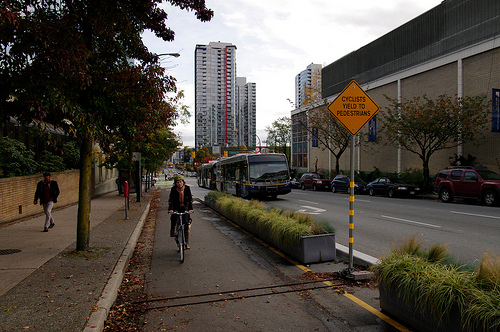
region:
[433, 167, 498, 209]
Red SUV parked on the side of a road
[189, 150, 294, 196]
Two mass transit buses driving on the road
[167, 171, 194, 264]
Woman riding a bicycle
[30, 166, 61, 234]
Man walking on a sidewalk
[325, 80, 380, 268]
Yellow sign on a metal pole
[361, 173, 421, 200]
Black car parked on the side of a road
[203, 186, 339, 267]
Plants in cement cement plant holder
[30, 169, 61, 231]
Man in a dark jacket and light pants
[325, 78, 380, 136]
Diamond shaped yellow sign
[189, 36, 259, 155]
Tall shiny city building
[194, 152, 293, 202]
Buses on the road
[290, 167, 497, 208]
Cars parked on the road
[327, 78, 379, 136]
Orange sign on a pole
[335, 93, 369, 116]
Words on the sign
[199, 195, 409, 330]
Yellow line on the road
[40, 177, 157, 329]
Curb on the sidewalk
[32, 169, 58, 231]
Man walking on the sidewalk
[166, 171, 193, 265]
Woman riding a bike on the road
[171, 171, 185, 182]
Hat on the woman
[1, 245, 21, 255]
Manhole cover on the sidewalk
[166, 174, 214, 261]
a person riding a bike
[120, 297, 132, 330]
leaves in the gutter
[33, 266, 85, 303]
leaves on the sidewalk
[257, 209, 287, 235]
green bushes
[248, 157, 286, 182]
a windshiled on the train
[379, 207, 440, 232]
a white line in the street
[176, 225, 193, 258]
a bike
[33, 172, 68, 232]
a man walking on the sidewalk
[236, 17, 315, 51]
clouds in the sky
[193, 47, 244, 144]
a tall building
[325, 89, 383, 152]
black and yellow sign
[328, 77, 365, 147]
black letters on sign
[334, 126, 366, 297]
grey and yellow pole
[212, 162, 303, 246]
green bushes near road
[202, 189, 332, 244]
green and grassy bush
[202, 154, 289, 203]
black and grey bus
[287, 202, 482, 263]
white lines on road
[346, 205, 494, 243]
road is light grey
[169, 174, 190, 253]
man is on bike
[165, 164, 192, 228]
man has black shirt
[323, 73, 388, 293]
The sign is orange and black.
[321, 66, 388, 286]
The sign is on a pole.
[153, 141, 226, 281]
The woman is riding a bike.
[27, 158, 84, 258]
The man is walking.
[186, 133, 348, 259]
Two busses are coming up the street.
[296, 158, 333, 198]
The car is parked.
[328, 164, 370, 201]
The car is parked.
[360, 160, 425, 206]
The car is parked.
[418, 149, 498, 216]
The car is parked.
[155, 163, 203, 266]
The woman is wearing a cap.